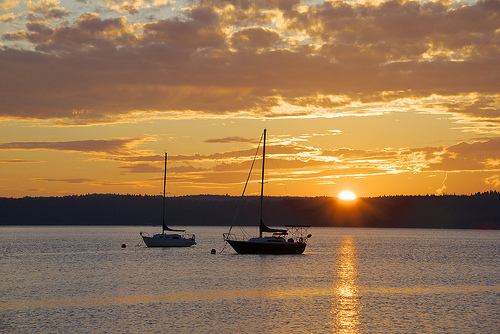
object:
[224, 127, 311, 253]
sailboat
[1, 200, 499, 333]
bay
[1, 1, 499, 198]
sunset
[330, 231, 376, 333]
reflection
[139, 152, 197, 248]
sailboat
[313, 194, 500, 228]
mangoves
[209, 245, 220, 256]
buoy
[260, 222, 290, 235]
sails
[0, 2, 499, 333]
sunrise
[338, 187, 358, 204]
sun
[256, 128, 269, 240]
sailboat mast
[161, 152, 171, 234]
mast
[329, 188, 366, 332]
sun is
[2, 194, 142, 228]
trees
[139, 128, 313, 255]
boats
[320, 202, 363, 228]
sunlight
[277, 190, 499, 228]
mangroves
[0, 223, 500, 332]
shore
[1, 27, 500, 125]
cloud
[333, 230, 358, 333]
cross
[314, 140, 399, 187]
clouds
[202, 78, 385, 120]
clouds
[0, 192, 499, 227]
hill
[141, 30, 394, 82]
clouds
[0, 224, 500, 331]
water